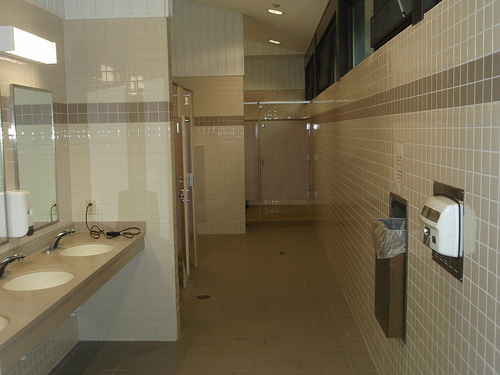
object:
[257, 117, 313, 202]
door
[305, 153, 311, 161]
hinge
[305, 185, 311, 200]
hinge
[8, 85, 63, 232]
mirror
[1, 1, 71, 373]
wall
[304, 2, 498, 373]
wall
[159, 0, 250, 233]
wall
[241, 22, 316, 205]
wall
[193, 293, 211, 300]
drain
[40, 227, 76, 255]
faucet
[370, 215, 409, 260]
liner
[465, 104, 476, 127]
tile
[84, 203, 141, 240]
electrical cord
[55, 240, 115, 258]
sink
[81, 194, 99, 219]
outlet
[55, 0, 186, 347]
wall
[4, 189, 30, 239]
paper towels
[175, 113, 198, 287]
door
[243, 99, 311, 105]
pipe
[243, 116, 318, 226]
stall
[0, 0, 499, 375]
bathroom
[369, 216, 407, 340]
garbage can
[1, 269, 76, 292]
sinks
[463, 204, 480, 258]
image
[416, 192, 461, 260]
hand dryer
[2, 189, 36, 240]
soap dispenser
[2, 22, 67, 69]
light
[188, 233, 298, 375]
round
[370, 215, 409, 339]
waste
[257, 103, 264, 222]
shower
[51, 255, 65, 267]
chrome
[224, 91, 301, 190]
four